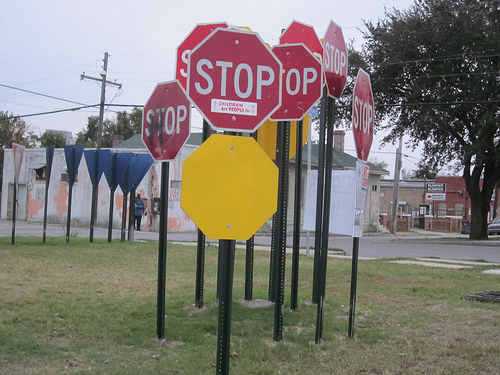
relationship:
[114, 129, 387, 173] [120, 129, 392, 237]
roof of building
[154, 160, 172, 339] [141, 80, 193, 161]
post holds stop sign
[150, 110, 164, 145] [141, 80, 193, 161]
tagging on stop sign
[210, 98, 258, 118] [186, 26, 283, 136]
sticker on stop sign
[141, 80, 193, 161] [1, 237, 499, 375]
stop sign on grass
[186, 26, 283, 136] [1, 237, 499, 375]
stop sign on grass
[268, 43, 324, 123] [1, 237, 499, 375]
stop sign on grass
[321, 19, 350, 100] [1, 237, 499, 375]
stop sign on grass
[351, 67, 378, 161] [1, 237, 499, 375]
stop sign on grass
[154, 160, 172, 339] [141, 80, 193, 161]
post on stop sign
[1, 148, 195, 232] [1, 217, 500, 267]
building on street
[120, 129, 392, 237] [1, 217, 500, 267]
building on street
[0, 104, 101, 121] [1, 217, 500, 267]
electrical line over street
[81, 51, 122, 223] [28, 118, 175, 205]
power pole behind signs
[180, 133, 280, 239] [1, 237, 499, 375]
sign on grass